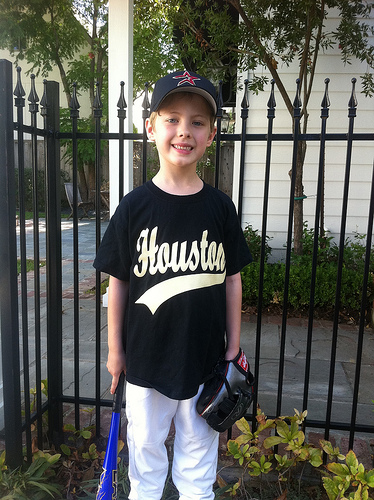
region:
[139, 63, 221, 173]
the head of a boy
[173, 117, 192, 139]
the nose of a boy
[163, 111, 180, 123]
the eye of a boy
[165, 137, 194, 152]
the mouth of a boy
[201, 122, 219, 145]
the ear of a boy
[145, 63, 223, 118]
a black baseball cap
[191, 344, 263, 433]
a black baseball glove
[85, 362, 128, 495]
a black and blue baseball bat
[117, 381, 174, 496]
the leg of a boy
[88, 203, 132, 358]
the arm of a boy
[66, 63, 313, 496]
Young boy in baseball clothes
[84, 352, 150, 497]
Blue baseball bat boy is holding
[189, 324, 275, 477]
Black mitt on boy's right hand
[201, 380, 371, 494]
Green plants next to boy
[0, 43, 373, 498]
Wrought iron fence behind boy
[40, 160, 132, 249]
Patio furniture behind the boy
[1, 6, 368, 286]
Trees behind the boy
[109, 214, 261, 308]
Name of team on the boy's shirt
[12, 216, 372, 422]
Patio area behind the boy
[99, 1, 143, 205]
white pillar behind the boy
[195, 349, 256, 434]
A black baseball mitt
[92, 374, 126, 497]
A blue baseball bat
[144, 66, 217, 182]
The head of a boy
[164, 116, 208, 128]
The two eyes of a boy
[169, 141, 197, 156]
The mouth of a boy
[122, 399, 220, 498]
White pants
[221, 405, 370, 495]
Several green plants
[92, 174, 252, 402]
A black tee shirt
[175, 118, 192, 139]
The nose of a boy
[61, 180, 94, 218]
A deck chair in the distance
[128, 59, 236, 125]
Boy wearing a baseball hat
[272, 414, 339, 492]
Plants in front of the fence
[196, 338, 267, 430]
Boy wearing a baseball glove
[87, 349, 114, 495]
Blue and black baseball bat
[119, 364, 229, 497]
White baseball pants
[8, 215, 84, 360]
Black bars behind the little boy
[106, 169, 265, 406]
Black t shirt with white writing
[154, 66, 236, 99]
Boy has star on hat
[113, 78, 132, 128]
Point on top of fence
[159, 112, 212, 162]
Boy smiling for the camera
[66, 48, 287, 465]
Kid in baseball uniform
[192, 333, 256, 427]
Boy wearing baseball glove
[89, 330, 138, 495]
Blue baseball bat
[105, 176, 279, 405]
Boy wearing black and white shirt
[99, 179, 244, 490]
Boy wearing white baseball pants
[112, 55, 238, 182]
Boy wearing black and red hat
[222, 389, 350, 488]
Plants on the ground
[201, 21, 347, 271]
Tree near a house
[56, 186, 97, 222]
A patio chair in the distance